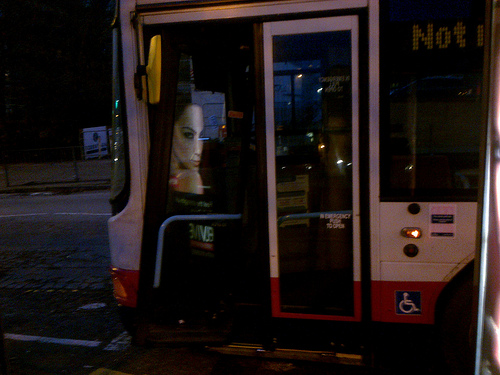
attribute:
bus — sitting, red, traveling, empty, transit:
[99, 14, 461, 339]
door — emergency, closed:
[259, 17, 365, 311]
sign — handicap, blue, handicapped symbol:
[383, 277, 428, 326]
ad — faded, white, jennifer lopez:
[174, 96, 215, 193]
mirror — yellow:
[125, 38, 170, 93]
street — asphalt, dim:
[35, 208, 109, 305]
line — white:
[19, 320, 74, 357]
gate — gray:
[41, 137, 95, 182]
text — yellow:
[396, 17, 491, 66]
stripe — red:
[352, 256, 449, 338]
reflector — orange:
[102, 273, 141, 312]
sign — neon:
[361, 22, 490, 59]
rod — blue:
[163, 208, 254, 233]